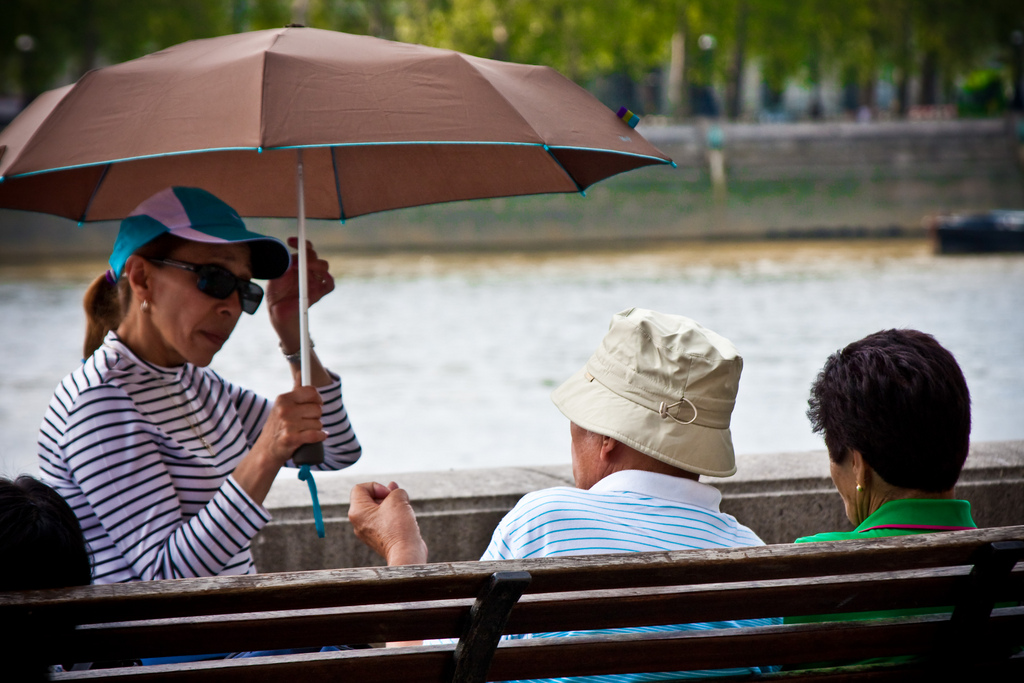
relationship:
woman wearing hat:
[36, 186, 364, 586] [102, 185, 286, 285]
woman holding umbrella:
[41, 201, 376, 616] [184, 213, 328, 479]